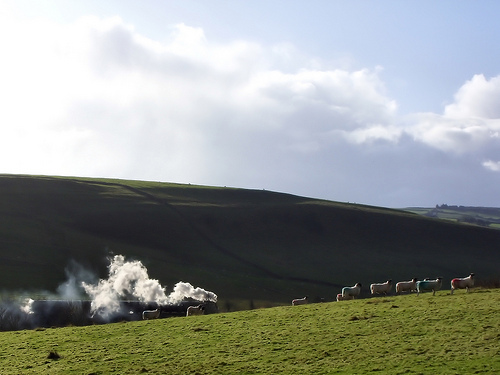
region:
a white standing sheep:
[449, 273, 478, 295]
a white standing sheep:
[415, 277, 442, 297]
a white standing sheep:
[393, 279, 415, 294]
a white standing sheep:
[367, 279, 393, 299]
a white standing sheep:
[339, 282, 362, 299]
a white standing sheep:
[290, 294, 307, 308]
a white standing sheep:
[334, 291, 353, 301]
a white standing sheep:
[184, 303, 207, 317]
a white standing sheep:
[140, 306, 158, 321]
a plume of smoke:
[4, 254, 217, 326]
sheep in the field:
[282, 288, 308, 313]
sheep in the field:
[188, 304, 210, 321]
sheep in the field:
[141, 304, 165, 324]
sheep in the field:
[345, 283, 360, 303]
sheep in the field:
[371, 281, 392, 303]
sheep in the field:
[423, 280, 444, 292]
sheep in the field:
[449, 271, 479, 294]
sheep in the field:
[336, 292, 343, 303]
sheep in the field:
[369, 280, 391, 292]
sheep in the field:
[413, 278, 440, 293]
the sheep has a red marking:
[448, 273, 465, 290]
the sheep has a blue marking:
[410, 278, 432, 293]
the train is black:
[48, 296, 94, 316]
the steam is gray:
[190, 284, 220, 306]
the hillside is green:
[271, 213, 326, 251]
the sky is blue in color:
[364, 16, 430, 57]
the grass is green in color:
[316, 323, 356, 351]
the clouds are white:
[195, 40, 245, 85]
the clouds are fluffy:
[398, 102, 458, 173]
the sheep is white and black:
[285, 290, 314, 312]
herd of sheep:
[276, 262, 481, 309]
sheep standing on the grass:
[280, 266, 483, 306]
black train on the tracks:
[3, 276, 230, 331]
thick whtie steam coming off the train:
[75, 249, 211, 324]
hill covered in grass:
[5, 167, 497, 327]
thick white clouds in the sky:
[4, 4, 499, 211]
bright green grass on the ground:
[3, 288, 499, 374]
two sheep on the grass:
[134, 297, 214, 320]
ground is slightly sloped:
[0, 281, 497, 373]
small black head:
[350, 279, 362, 291]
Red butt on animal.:
[447, 270, 470, 293]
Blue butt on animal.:
[411, 272, 441, 303]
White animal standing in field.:
[396, 270, 419, 297]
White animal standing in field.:
[366, 270, 391, 310]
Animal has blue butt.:
[340, 270, 360, 296]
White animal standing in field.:
[286, 289, 331, 338]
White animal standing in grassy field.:
[141, 300, 175, 331]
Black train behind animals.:
[24, 281, 246, 327]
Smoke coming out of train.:
[190, 273, 220, 320]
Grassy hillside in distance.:
[67, 160, 397, 286]